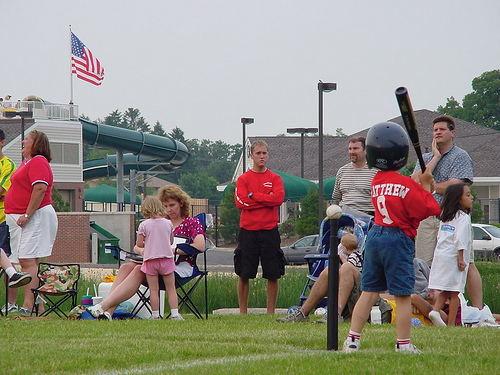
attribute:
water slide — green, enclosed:
[80, 119, 189, 179]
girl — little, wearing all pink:
[135, 195, 186, 320]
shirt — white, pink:
[135, 217, 176, 261]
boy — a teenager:
[232, 139, 286, 317]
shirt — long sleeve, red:
[232, 169, 286, 230]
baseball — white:
[325, 202, 342, 221]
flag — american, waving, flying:
[68, 30, 106, 87]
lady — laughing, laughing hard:
[1, 130, 60, 321]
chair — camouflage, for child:
[32, 259, 82, 316]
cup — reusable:
[80, 295, 96, 319]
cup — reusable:
[93, 294, 102, 304]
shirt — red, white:
[370, 168, 442, 239]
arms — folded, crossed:
[234, 171, 286, 210]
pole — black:
[316, 89, 324, 228]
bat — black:
[392, 83, 436, 197]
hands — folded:
[244, 188, 275, 201]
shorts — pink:
[141, 256, 177, 276]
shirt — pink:
[4, 154, 55, 216]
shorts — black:
[232, 226, 288, 281]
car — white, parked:
[471, 221, 499, 262]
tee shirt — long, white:
[425, 212, 472, 292]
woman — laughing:
[6, 129, 63, 316]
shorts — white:
[3, 205, 61, 259]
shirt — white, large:
[428, 209, 474, 297]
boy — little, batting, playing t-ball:
[342, 122, 441, 356]